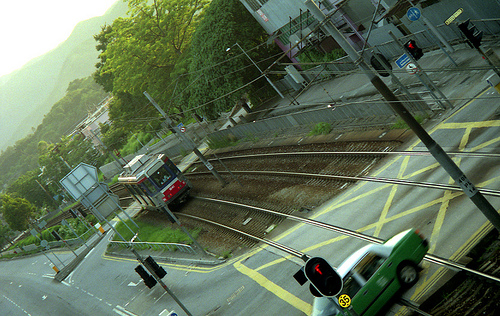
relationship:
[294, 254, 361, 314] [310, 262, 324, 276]
stop sign signaling red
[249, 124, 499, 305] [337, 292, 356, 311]
walkway has sign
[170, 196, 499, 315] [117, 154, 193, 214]
tracks has train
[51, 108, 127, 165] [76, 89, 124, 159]
background has building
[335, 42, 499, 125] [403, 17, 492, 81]
street has lights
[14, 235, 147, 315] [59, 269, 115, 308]
street has dotted lines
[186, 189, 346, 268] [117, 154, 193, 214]
tracks have train car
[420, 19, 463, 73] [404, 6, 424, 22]
pole has sign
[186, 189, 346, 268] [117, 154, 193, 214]
tracks have tram car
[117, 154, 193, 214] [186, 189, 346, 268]
train on tracks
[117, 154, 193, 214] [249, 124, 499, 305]
train going across crossing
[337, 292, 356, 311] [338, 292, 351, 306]
sign has number 35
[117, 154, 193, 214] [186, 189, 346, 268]
train car on tracks